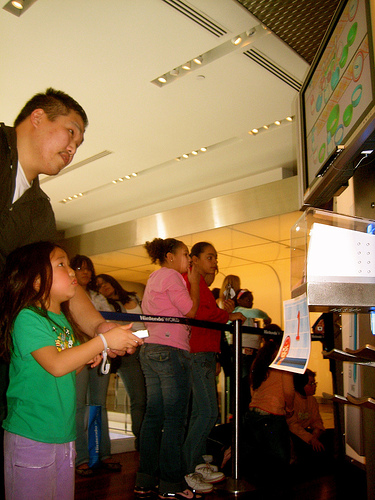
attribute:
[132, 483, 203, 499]
shoes — pink, black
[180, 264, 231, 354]
jacket — red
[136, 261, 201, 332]
shirt — pink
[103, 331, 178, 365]
controller — on the lady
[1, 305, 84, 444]
shirt — green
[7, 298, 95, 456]
shirt — green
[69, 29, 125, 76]
ceiling — white 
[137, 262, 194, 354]
shirt — pink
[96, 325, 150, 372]
wii — on the lady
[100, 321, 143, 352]
hand — with remote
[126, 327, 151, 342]
wii remote — in a hand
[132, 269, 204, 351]
pink shirt — on the lady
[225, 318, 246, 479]
pole — shining, black, slender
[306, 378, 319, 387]
glasses — on the lady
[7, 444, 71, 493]
pants — on the girl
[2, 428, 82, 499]
pants — on the lady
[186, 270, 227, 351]
jacket — red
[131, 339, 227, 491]
jeans — blue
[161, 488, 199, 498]
sneaker — pink and black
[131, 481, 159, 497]
sneaker — pink and black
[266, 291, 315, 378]
paper — number one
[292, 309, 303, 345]
1 — on the paper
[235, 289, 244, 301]
headband — pink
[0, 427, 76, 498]
pants — purple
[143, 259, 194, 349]
shirt — pink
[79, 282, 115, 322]
shirt — white